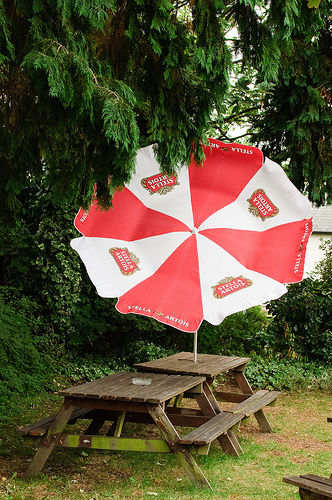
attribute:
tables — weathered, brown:
[19, 350, 283, 490]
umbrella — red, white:
[69, 136, 314, 363]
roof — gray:
[187, 2, 331, 234]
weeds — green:
[2, 361, 331, 429]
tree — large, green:
[0, 0, 330, 240]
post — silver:
[193, 332, 200, 361]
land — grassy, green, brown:
[0, 365, 330, 499]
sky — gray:
[145, 0, 281, 38]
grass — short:
[2, 388, 329, 500]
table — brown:
[134, 338, 283, 433]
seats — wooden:
[180, 385, 285, 456]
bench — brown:
[280, 471, 331, 500]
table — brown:
[19, 375, 243, 476]